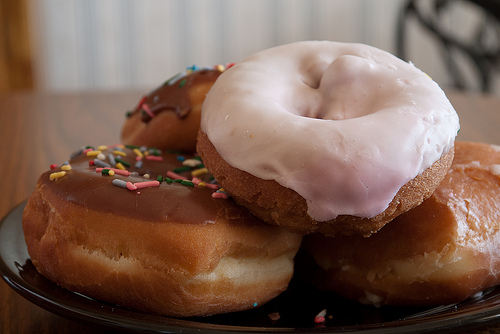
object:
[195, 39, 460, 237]
donut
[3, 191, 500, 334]
plate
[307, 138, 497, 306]
donut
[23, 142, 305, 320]
donut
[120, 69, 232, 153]
donut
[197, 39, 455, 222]
frosting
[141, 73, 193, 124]
chocolate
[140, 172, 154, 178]
sprinkle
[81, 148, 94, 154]
sprinkle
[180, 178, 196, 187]
sprinkle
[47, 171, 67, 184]
sprinkle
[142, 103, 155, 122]
sprinkle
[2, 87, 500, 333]
table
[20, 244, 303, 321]
bottom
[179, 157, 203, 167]
sprinkles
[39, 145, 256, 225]
frosting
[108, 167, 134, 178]
sprinkle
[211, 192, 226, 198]
sprinkle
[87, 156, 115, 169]
sprinkle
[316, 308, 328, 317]
sprinkle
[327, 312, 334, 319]
sprinkle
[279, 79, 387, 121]
hole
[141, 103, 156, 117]
sprinkles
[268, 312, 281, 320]
crumbs